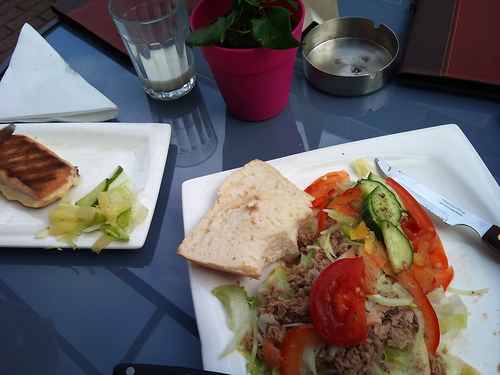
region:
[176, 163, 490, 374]
a brightly colored salad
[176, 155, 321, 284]
a piece of bread with a bite taken out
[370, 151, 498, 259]
a steak knife on a plate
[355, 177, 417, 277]
a few chunks of zucchini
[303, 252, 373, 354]
a slice of tomato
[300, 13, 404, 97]
a steel ash tray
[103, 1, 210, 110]
a drinking glass filled with liquid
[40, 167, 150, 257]
a group of vegetables on a plate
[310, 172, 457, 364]
a group of vegetables on a plate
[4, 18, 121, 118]
a folded napkin on a table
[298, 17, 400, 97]
A silver empty ashtray.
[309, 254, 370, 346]
Reddist slice of tomato on top of meat.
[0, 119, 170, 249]
A white square plate on a table with less food on it.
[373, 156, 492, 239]
A silver blade on a knife.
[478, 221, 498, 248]
A black end of a handle.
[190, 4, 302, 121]
A red pot with a flower in it.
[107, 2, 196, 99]
A clear glass of milk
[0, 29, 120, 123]
A triangle napkin on the table.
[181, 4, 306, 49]
A green leafy plant in a pot.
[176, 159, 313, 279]
A light colored piece of bread with bites taken out of it.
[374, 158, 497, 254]
part of a knife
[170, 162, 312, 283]
a piece of bread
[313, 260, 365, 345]
a red tomato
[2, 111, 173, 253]
a white plate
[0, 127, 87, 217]
a piece of meat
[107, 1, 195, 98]
a tall glass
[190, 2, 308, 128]
a pink potted plant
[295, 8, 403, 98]
a small gray tray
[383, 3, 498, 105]
part of a brown and black book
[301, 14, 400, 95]
empty silver ashtray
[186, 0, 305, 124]
bright red flower pot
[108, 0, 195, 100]
mostly empty glass of milk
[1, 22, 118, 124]
white napkin folded into a triangle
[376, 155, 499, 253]
silver knife with a black handle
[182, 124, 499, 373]
square white plate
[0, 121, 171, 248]
rectangular white plate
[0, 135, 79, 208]
panini on rectangular plate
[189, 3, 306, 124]
green leaes in pot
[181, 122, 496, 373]
square white plate of food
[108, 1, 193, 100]
glass with small amount of milk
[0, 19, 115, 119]
white triangle shaped napkin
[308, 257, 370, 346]
slice of red tomato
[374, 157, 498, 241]
silver blade of knife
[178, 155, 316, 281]
bread with bites missing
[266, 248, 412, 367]
pile of chopped meat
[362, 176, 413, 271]
half slices of cucumbers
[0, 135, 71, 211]
top of grilled sandwich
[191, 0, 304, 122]
A dark pink flower pot.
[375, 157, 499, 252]
Black and silver serrated knife.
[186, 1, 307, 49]
Green leafy plant in a pink pot.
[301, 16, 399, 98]
Silver round ashtray.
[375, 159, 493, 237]
Silver end of a knife.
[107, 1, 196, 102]
Clear glass of milk.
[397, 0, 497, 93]
Black a dark red book on the table next to an ashtray.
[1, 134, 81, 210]
Pice of chicken on a white plate.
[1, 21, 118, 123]
Triangle shaped white napkin.